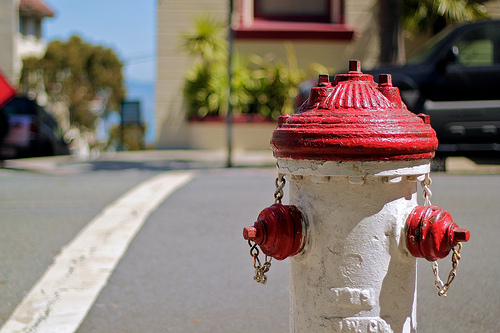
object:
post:
[222, 0, 239, 169]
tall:
[219, 0, 237, 168]